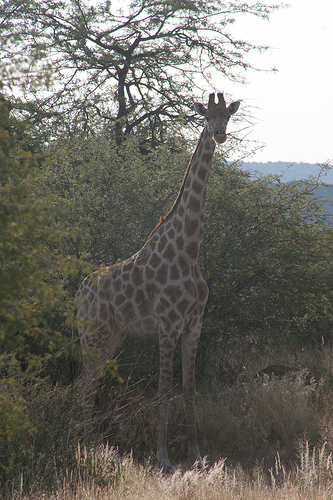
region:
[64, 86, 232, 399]
giraffe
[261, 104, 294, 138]
white clouds in blue sky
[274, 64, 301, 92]
white clouds in blue sky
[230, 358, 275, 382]
brown and yellow long grass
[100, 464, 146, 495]
brown and yellow long grass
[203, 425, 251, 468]
brown and yellow long grass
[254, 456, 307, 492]
brown and yellow long grass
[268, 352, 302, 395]
brown and yellow long grass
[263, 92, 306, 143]
white clouds in blue sky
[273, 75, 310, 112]
white clouds in blue sky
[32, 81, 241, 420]
brown giraffe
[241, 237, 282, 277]
green leaves on brown tree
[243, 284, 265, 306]
green leaves on brown tree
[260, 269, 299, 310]
green leaves on brown tree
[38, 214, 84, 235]
green leaves on brown tree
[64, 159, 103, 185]
green leaves on brown tree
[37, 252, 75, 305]
green leaves on brown tree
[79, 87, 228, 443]
brown spotted giraffe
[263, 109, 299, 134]
white clouds in blue sky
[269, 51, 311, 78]
white clouds in blue sky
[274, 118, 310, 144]
white clouds in blue sky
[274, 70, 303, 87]
white clouds in blue sky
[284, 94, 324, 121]
white clouds in blue sky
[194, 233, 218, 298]
Big giraffe standing in the yard with trees.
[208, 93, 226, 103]
two horns on a giraffe's head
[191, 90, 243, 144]
a giraffe's head facing the camera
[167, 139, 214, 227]
a giraffe's elongated neck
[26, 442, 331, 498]
illuminated brown grass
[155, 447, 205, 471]
the front feet of a giraffe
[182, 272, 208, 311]
the bony breastplate of a giraffe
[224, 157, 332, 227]
rolling hills in the distance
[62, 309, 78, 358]
the thin tail of a giraffe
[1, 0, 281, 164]
a tall brown and green tree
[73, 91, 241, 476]
an adult giraffe standing in the woods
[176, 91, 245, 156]
the head of a giraffe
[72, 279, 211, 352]
the body of a giraffe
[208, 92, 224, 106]
Horns on a giraffe.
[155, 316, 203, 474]
Front two giraffe legs.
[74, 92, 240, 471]
Tall brown and white giraffe.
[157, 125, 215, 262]
A tall brown and white giraffe neck.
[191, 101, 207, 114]
A giraffes right ear.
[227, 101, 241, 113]
A giraffes left ear.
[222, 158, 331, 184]
Distant grey colored land.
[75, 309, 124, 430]
Back legs of a brown and white giraffe.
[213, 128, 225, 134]
Black giraffe nostrils.